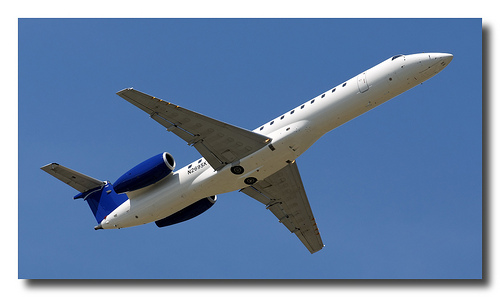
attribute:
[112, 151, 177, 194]
engine — blue jet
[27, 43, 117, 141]
clouds — white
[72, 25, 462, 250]
airplane — white, blue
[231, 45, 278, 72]
sky — blue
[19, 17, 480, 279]
sky — blue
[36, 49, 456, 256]
jet — white, blue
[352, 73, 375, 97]
door — closed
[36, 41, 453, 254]
airplane — white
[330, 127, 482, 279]
sky — blue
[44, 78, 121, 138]
clouds — white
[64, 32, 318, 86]
sky — blue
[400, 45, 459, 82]
nose — cone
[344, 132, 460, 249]
clouds — white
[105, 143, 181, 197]
engine — blue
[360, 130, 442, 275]
sky — blue